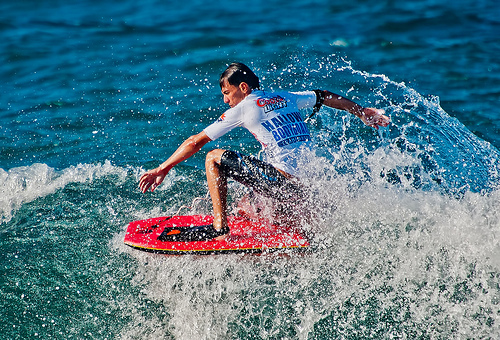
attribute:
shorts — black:
[218, 146, 313, 204]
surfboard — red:
[106, 197, 437, 336]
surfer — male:
[137, 60, 389, 242]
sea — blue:
[1, 0, 496, 339]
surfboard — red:
[99, 201, 401, 258]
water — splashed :
[299, 144, 496, 324]